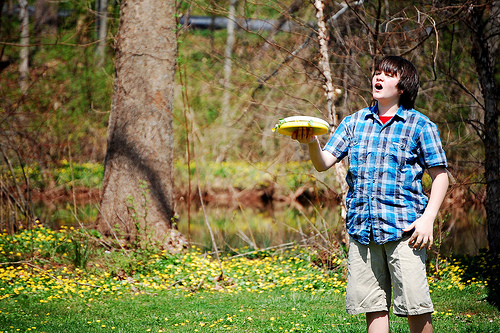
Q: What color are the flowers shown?
A: Yellow.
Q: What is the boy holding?
A: A frisbee.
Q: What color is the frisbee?
A: Yellow.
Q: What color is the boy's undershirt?
A: Red.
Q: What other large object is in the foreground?
A: Tree.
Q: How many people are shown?
A: One.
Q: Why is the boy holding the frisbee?
A: To throw it.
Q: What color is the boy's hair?
A: Brown.